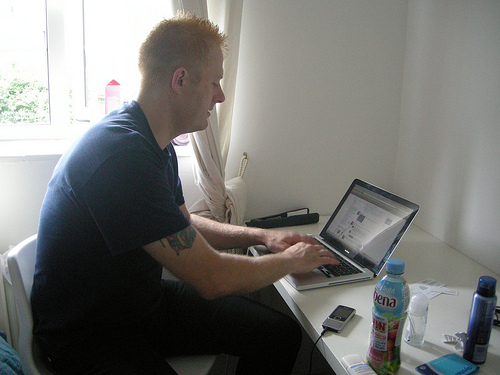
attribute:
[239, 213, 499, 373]
table — white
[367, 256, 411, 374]
water bottle — light blue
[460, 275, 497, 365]
spray can — blue, steely blue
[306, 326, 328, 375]
cord — black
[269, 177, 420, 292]
laptop — silver, black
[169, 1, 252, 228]
curtain — white, twisted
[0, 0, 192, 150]
window — open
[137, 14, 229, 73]
hair — red, orange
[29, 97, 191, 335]
shirt — navy blue, black, navy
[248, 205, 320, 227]
stapler — black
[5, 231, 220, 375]
chair — white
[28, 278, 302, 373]
pants — black